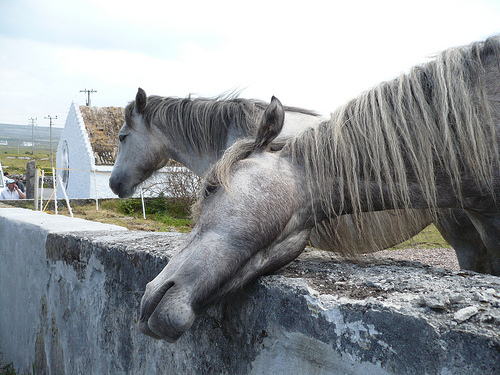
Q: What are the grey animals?
A: Horses.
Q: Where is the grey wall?
A: Under the horse's head.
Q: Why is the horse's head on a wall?
A: He is scratching.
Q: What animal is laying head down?
A: A horse.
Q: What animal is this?
A: Horse.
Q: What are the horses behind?
A: A wall.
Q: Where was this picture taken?
A: A yard.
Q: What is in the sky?
A: Clouds.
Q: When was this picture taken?
A: Daytime.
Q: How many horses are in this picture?
A: Two.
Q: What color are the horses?
A: White.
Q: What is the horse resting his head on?
A: A cement wall.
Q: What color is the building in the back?
A: White.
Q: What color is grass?
A: Green.